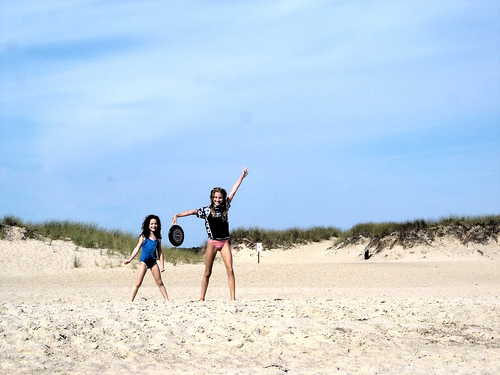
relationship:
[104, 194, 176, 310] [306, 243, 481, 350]
girl on beach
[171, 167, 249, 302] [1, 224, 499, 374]
girl on beach